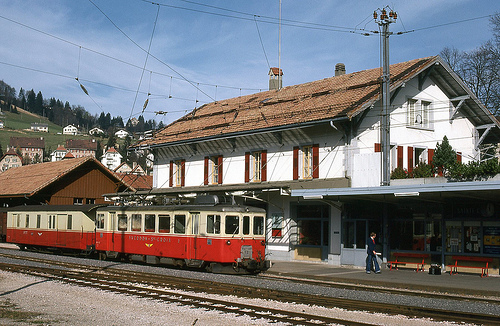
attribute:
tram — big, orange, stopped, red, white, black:
[7, 186, 270, 274]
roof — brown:
[142, 57, 499, 149]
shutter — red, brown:
[313, 142, 319, 179]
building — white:
[139, 56, 497, 265]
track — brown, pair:
[242, 271, 496, 300]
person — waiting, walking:
[364, 229, 379, 275]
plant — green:
[429, 134, 469, 181]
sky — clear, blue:
[1, 1, 498, 124]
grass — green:
[0, 110, 93, 153]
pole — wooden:
[377, 26, 390, 186]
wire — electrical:
[146, 1, 385, 41]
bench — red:
[384, 252, 430, 270]